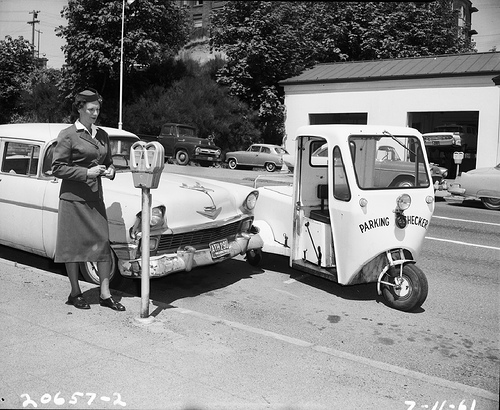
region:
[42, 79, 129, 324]
meter maid wearing her uniform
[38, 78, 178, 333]
meter maid next to double parking meter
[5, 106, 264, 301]
car parked next to a parking meter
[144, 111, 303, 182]
cars parallel parked on the street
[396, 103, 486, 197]
car on a lift in the shop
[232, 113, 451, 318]
parking clerk's small cart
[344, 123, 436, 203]
single wiper on cart's windshield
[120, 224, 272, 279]
heavy chrome bumper on a car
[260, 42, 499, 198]
car maintenance shop building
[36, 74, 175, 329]
meter maid checking the parking meter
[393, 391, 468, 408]
Date is 7-11-61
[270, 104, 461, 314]
The vehicle is a parking checker.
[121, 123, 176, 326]
Two meters attached to the pole.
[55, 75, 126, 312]
The woman is parking patrol.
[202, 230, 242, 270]
license plate reads ATH298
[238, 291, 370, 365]
The asphalt is dry.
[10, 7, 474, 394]
The color is black and white.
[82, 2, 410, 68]
Many leaves on the tree.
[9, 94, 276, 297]
The car received a parking fine.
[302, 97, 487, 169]
The building is a repair garage.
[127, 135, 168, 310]
A parking meter being checked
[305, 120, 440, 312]
Parking checker vehicle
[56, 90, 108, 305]
Parking meter officer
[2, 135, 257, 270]
Car being checked by meter maid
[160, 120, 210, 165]
Dark colored pick up truck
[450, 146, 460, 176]
Meter in front of garage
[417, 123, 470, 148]
Car up on lift in garage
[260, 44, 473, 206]
A garage servicing a car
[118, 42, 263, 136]
Hill next to garage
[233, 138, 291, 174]
Car parked in front of pick-up truck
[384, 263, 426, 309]
Thick rubber tire with metal rim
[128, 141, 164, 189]
Old change parking meter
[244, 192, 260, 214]
Headlight on front of car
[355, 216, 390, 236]
Word parking on front of cart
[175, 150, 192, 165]
White wall tire with solid hub cap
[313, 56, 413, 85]
Long metal roof on garage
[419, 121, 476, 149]
Car raised on car lift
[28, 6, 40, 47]
Tall electrical pole in distance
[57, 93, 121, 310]
Lady putting change in parking meter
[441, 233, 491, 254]
Line dividing road way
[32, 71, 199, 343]
Meter maid tending to a meter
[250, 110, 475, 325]
Parking checker mobile double parked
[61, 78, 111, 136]
Spiffy hat from another era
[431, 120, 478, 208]
Parking meter on the other side of street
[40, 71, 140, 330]
Meter maid very properly dressed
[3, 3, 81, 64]
Telephone pole supporting wires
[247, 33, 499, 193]
Auto repair business on the other side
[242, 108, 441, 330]
Two wheels in back and one in front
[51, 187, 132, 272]
Skirt past the knees.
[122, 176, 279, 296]
Old car from the 1950s